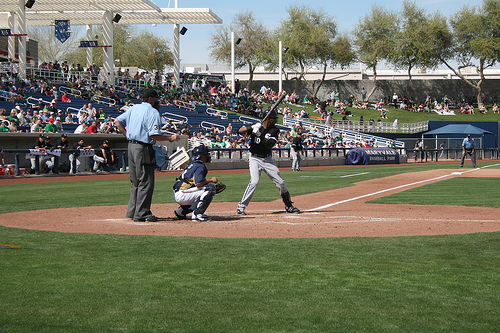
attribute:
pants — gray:
[123, 142, 161, 234]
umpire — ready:
[123, 92, 159, 224]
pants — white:
[244, 157, 291, 206]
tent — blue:
[423, 118, 488, 165]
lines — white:
[316, 170, 483, 300]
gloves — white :
[245, 116, 272, 143]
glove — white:
[249, 120, 264, 130]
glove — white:
[253, 126, 263, 136]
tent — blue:
[417, 120, 487, 162]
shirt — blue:
[112, 104, 167, 137]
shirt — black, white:
[245, 122, 278, 158]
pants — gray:
[237, 152, 292, 214]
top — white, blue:
[179, 159, 207, 183]